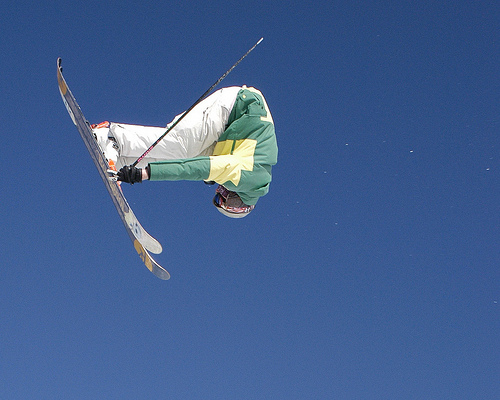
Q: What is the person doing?
A: Skiing.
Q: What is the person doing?
A: Adjusting skis.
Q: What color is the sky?
A: Blue.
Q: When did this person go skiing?
A: During the day.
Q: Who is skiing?
A: A man.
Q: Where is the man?
A: In the sky.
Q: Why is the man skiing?
A: Hobby.